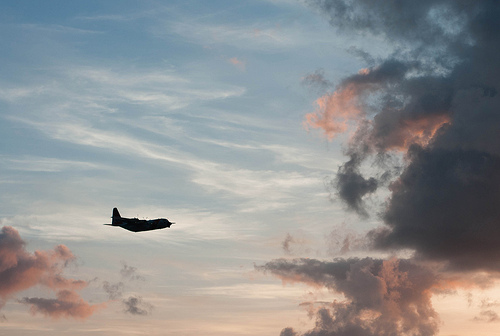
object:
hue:
[431, 281, 483, 332]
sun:
[306, 111, 347, 134]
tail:
[112, 207, 121, 225]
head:
[153, 217, 174, 230]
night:
[0, 0, 500, 336]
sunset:
[336, 67, 432, 220]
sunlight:
[231, 281, 268, 332]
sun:
[404, 116, 444, 147]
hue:
[303, 83, 370, 139]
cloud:
[0, 0, 500, 336]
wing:
[169, 222, 175, 224]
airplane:
[103, 207, 176, 234]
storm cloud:
[332, 7, 483, 285]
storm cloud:
[252, 256, 444, 334]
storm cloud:
[301, 58, 422, 143]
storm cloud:
[304, 1, 448, 47]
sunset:
[2, 280, 484, 330]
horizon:
[1, 309, 483, 334]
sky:
[2, 2, 500, 336]